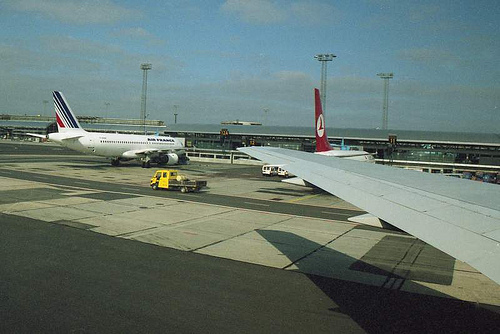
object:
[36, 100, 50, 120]
airplane tower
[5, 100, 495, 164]
roof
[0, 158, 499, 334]
runway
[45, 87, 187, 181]
plane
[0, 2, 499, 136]
clouds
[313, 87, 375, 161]
airplane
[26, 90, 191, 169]
airplane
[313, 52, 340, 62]
watchtowers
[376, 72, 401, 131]
tower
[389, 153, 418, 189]
ground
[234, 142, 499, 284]
plane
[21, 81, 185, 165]
plane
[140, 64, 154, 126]
airplane towers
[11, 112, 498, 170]
roof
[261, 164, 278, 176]
bus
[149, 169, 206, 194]
luggage truck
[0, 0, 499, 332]
airport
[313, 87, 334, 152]
wing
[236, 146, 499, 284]
wing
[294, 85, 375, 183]
plane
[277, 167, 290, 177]
car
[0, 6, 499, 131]
sky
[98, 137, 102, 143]
window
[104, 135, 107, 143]
window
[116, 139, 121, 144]
window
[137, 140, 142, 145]
window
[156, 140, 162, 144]
window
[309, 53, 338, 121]
tower